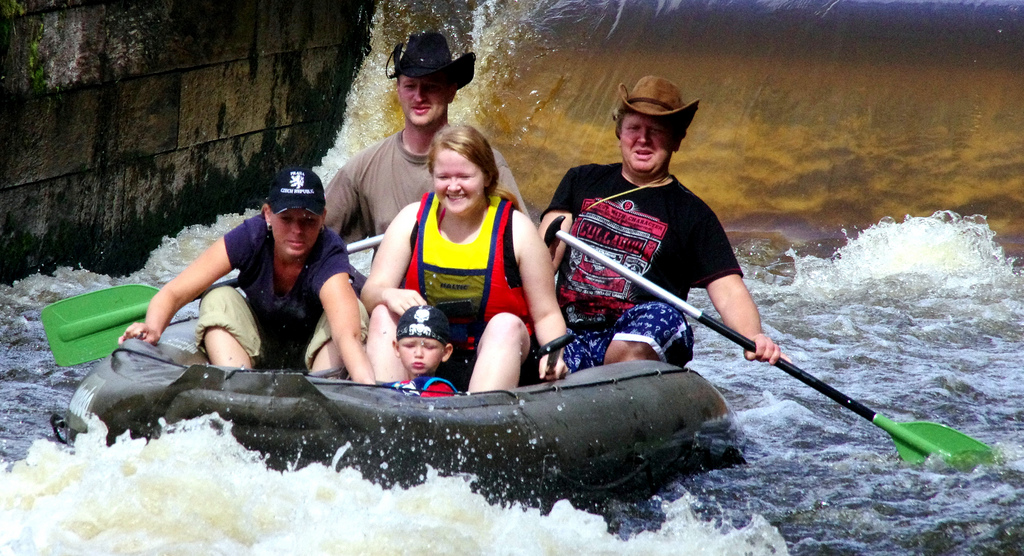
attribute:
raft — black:
[50, 331, 734, 505]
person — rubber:
[538, 71, 782, 375]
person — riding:
[325, 27, 528, 239]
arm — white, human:
[312, 269, 380, 386]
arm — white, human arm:
[118, 236, 229, 342]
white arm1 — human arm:
[505, 209, 570, 356]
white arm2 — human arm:
[362, 197, 419, 306]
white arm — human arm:
[710, 272, 752, 333]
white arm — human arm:
[543, 209, 570, 266]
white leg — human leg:
[198, 313, 257, 372]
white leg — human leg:
[307, 337, 334, 370]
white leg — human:
[366, 299, 402, 386]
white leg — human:
[468, 312, 530, 393]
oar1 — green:
[27, 249, 199, 373]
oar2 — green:
[544, 224, 985, 463]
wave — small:
[13, 430, 587, 552]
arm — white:
[511, 208, 566, 379]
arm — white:
[358, 199, 428, 321]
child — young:
[377, 303, 466, 401]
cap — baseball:
[400, 306, 453, 345]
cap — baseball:
[272, 164, 327, 210]